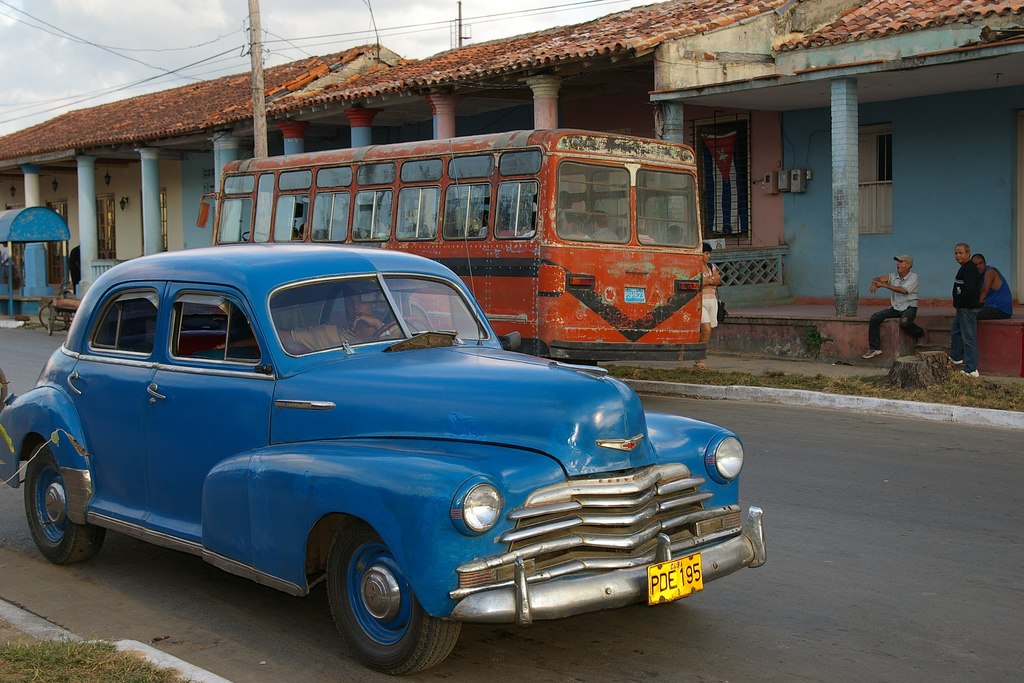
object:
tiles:
[106, 78, 243, 110]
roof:
[0, 43, 411, 162]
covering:
[0, 206, 72, 243]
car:
[0, 245, 767, 675]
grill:
[447, 462, 770, 621]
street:
[3, 287, 1024, 683]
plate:
[647, 551, 704, 607]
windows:
[88, 286, 160, 366]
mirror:
[195, 202, 208, 227]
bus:
[195, 129, 702, 361]